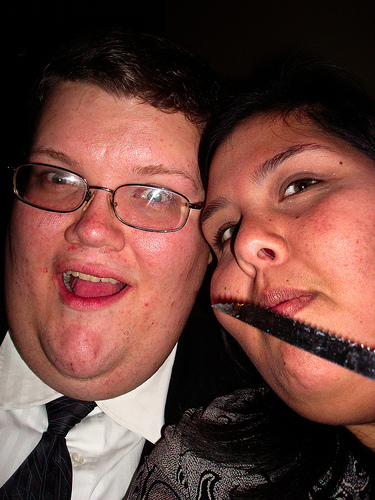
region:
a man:
[57, 263, 152, 433]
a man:
[86, 282, 154, 389]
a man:
[99, 245, 160, 361]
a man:
[95, 293, 172, 496]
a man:
[105, 348, 193, 485]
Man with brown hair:
[2, 56, 201, 299]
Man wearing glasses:
[4, 94, 202, 264]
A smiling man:
[15, 151, 186, 332]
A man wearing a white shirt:
[8, 152, 151, 481]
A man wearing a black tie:
[11, 165, 112, 496]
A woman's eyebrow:
[243, 133, 346, 180]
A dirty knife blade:
[208, 287, 373, 397]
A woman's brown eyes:
[207, 161, 345, 244]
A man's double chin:
[4, 308, 173, 421]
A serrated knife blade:
[209, 273, 374, 387]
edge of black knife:
[196, 294, 262, 321]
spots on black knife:
[270, 324, 351, 359]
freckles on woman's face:
[284, 212, 338, 245]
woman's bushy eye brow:
[244, 132, 325, 163]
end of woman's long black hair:
[173, 429, 247, 478]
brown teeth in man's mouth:
[60, 263, 126, 291]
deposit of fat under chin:
[13, 335, 159, 404]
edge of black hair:
[96, 84, 196, 118]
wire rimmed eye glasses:
[19, 151, 196, 244]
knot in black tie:
[28, 394, 114, 445]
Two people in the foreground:
[5, 57, 373, 402]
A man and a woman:
[6, 48, 372, 438]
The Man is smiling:
[34, 250, 145, 327]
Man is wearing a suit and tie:
[1, 330, 244, 499]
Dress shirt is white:
[1, 332, 180, 499]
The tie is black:
[1, 384, 126, 496]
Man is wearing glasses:
[8, 151, 206, 256]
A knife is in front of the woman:
[209, 272, 374, 384]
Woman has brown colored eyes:
[187, 157, 352, 250]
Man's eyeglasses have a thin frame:
[0, 152, 213, 249]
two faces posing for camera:
[12, 36, 369, 476]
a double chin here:
[1, 311, 170, 396]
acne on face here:
[35, 240, 185, 334]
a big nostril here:
[251, 229, 285, 267]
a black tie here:
[4, 393, 95, 498]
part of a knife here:
[204, 285, 371, 381]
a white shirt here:
[2, 338, 160, 495]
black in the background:
[4, 3, 374, 109]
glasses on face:
[12, 151, 204, 237]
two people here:
[6, 40, 366, 498]